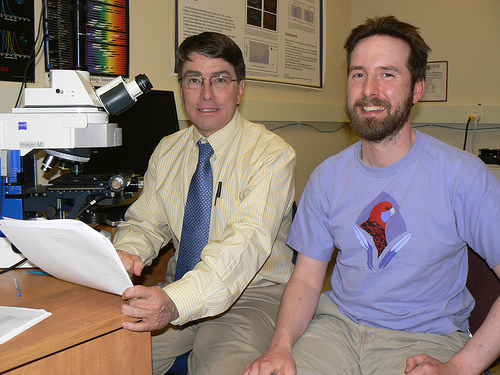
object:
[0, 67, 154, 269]
microscope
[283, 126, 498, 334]
tee shirt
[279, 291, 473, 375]
pants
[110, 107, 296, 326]
dress shirt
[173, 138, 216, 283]
tie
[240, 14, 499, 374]
man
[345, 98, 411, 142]
beard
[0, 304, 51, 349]
papers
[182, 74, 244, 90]
glasses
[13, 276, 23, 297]
pen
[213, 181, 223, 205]
pen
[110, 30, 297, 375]
man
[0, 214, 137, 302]
paper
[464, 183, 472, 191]
outlet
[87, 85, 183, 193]
monitor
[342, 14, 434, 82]
hair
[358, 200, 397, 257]
bird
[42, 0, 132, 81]
poster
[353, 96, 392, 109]
mustache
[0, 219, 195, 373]
desk